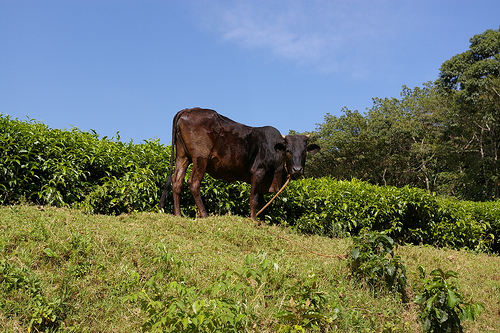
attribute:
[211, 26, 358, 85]
cloud — white, puffy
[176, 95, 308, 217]
cow — skinny, brown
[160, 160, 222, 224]
legs — back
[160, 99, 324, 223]
cow — camera-looking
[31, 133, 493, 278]
hedge — green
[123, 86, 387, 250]
animal — brown, dark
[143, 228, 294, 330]
grass — green, tan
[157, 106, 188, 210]
tail — brown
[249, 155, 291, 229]
rope — brown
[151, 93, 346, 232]
cow — black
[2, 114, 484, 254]
bushes — hedged, green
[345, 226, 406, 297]
bush — tiny, green